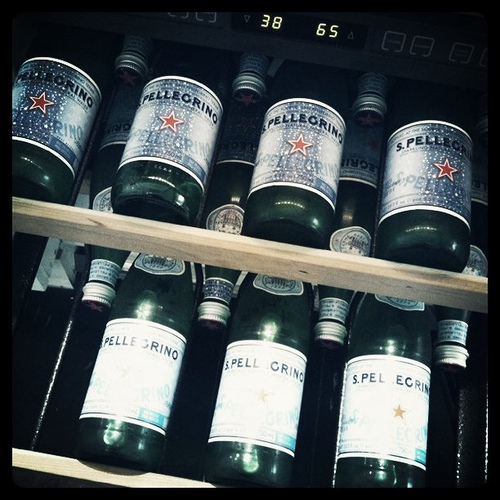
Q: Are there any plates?
A: No, there are no plates.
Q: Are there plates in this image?
A: No, there are no plates.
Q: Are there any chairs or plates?
A: No, there are no plates or chairs.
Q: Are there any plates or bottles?
A: Yes, there is a bottle.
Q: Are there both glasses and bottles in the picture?
A: No, there is a bottle but no glasses.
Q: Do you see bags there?
A: No, there are no bags.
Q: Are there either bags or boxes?
A: No, there are no bags or boxes.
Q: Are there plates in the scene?
A: No, there are no plates.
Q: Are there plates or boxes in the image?
A: No, there are no plates or boxes.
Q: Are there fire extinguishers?
A: No, there are no fire extinguishers.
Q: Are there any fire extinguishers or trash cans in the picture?
A: No, there are no fire extinguishers or trash cans.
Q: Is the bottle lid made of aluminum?
A: Yes, the lid is made of aluminum.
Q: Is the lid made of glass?
A: No, the lid is made of aluminum.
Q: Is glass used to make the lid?
A: No, the lid is made of aluminum.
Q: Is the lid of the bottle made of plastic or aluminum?
A: The lid is made of aluminum.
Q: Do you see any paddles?
A: No, there are no paddles.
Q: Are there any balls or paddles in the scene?
A: No, there are no paddles or balls.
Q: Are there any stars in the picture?
A: Yes, there is a star.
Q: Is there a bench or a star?
A: Yes, there is a star.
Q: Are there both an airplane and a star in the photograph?
A: No, there is a star but no airplanes.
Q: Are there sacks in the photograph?
A: No, there are no sacks.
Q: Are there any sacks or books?
A: No, there are no sacks or books.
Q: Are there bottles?
A: Yes, there is a bottle.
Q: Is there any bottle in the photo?
A: Yes, there is a bottle.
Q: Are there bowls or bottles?
A: Yes, there is a bottle.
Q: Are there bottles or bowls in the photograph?
A: Yes, there is a bottle.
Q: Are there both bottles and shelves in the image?
A: Yes, there are both a bottle and a shelf.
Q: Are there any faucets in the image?
A: No, there are no faucets.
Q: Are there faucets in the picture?
A: No, there are no faucets.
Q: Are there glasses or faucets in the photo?
A: No, there are no faucets or glasses.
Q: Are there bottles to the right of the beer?
A: Yes, there is a bottle to the right of the beer.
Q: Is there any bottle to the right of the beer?
A: Yes, there is a bottle to the right of the beer.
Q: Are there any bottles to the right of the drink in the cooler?
A: Yes, there is a bottle to the right of the beer.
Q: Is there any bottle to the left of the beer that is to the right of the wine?
A: No, the bottle is to the right of the beer.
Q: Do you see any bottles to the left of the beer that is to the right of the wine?
A: No, the bottle is to the right of the beer.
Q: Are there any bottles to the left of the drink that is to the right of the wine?
A: No, the bottle is to the right of the beer.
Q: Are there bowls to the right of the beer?
A: No, there is a bottle to the right of the beer.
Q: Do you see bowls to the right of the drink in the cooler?
A: No, there is a bottle to the right of the beer.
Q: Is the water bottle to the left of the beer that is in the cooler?
A: No, the bottle is to the right of the beer.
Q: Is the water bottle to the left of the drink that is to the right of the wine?
A: No, the bottle is to the right of the beer.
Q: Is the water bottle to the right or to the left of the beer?
A: The bottle is to the right of the beer.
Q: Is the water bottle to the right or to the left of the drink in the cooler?
A: The bottle is to the right of the beer.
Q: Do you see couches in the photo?
A: No, there are no couches.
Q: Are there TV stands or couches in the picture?
A: No, there are no couches or TV stands.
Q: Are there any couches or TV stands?
A: No, there are no couches or TV stands.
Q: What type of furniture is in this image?
A: The furniture is a shelf.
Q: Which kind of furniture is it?
A: The piece of furniture is a shelf.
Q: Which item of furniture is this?
A: That is a shelf.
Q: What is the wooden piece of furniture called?
A: The piece of furniture is a shelf.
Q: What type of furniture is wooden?
A: The furniture is a shelf.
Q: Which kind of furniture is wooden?
A: The furniture is a shelf.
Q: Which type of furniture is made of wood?
A: The furniture is a shelf.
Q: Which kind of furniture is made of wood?
A: The furniture is a shelf.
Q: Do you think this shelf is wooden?
A: Yes, the shelf is wooden.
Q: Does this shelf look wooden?
A: Yes, the shelf is wooden.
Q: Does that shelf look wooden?
A: Yes, the shelf is wooden.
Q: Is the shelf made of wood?
A: Yes, the shelf is made of wood.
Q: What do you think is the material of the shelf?
A: The shelf is made of wood.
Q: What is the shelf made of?
A: The shelf is made of wood.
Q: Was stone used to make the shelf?
A: No, the shelf is made of wood.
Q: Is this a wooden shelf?
A: Yes, this is a wooden shelf.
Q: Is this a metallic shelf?
A: No, this is a wooden shelf.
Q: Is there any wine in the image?
A: Yes, there is wine.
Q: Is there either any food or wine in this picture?
A: Yes, there is wine.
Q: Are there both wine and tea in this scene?
A: No, there is wine but no tea.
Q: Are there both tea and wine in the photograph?
A: No, there is wine but no tea.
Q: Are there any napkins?
A: No, there are no napkins.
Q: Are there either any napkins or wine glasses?
A: No, there are no napkins or wine glasses.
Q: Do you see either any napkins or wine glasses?
A: No, there are no napkins or wine glasses.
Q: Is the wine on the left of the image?
A: Yes, the wine is on the left of the image.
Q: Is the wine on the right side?
A: No, the wine is on the left of the image.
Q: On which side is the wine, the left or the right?
A: The wine is on the left of the image.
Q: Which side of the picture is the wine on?
A: The wine is on the left of the image.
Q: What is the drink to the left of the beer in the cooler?
A: The drink is wine.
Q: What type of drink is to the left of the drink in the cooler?
A: The drink is wine.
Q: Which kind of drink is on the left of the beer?
A: The drink is wine.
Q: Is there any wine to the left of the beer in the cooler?
A: Yes, there is wine to the left of the beer.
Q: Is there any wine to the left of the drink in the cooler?
A: Yes, there is wine to the left of the beer.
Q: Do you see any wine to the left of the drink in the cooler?
A: Yes, there is wine to the left of the beer.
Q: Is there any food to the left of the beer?
A: No, there is wine to the left of the beer.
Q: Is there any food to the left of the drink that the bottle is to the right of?
A: No, there is wine to the left of the beer.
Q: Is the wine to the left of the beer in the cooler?
A: Yes, the wine is to the left of the beer.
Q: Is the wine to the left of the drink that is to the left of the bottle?
A: Yes, the wine is to the left of the beer.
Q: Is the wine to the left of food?
A: No, the wine is to the left of the beer.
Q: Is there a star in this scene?
A: Yes, there is a star.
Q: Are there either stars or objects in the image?
A: Yes, there is a star.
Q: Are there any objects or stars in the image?
A: Yes, there is a star.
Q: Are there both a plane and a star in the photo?
A: No, there is a star but no airplanes.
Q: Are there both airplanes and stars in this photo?
A: No, there is a star but no airplanes.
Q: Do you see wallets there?
A: No, there are no wallets.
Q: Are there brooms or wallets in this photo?
A: No, there are no wallets or brooms.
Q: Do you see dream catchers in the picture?
A: No, there are no dream catchers.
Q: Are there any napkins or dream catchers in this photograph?
A: No, there are no dream catchers or napkins.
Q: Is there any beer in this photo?
A: Yes, there is beer.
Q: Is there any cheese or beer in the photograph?
A: Yes, there is beer.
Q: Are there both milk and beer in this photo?
A: No, there is beer but no milk.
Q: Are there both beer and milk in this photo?
A: No, there is beer but no milk.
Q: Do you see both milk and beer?
A: No, there is beer but no milk.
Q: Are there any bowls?
A: No, there are no bowls.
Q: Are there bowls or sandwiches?
A: No, there are no bowls or sandwiches.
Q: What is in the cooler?
A: The beer is in the cooler.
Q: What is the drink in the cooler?
A: The drink is beer.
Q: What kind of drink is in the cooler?
A: The drink is beer.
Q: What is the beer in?
A: The beer is in the cooler.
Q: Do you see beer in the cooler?
A: Yes, there is beer in the cooler.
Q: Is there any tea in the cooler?
A: No, there is beer in the cooler.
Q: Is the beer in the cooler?
A: Yes, the beer is in the cooler.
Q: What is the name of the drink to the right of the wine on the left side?
A: The drink is beer.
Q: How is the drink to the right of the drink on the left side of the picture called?
A: The drink is beer.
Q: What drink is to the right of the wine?
A: The drink is beer.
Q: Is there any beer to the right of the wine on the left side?
A: Yes, there is beer to the right of the wine.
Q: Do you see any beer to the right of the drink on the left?
A: Yes, there is beer to the right of the wine.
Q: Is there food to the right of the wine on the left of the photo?
A: No, there is beer to the right of the wine.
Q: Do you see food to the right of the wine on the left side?
A: No, there is beer to the right of the wine.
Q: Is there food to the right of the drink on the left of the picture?
A: No, there is beer to the right of the wine.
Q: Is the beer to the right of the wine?
A: Yes, the beer is to the right of the wine.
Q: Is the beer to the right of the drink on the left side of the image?
A: Yes, the beer is to the right of the wine.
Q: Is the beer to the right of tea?
A: No, the beer is to the right of the wine.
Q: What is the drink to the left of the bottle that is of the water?
A: The drink is beer.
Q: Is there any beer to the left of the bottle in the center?
A: Yes, there is beer to the left of the bottle.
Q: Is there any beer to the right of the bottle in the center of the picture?
A: No, the beer is to the left of the bottle.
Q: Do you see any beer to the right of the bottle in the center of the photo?
A: No, the beer is to the left of the bottle.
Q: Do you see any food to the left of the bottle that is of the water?
A: No, there is beer to the left of the bottle.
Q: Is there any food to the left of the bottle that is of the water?
A: No, there is beer to the left of the bottle.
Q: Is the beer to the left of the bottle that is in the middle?
A: Yes, the beer is to the left of the bottle.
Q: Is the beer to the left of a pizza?
A: No, the beer is to the left of the bottle.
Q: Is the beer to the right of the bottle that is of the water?
A: No, the beer is to the left of the bottle.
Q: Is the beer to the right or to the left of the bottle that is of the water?
A: The beer is to the left of the bottle.